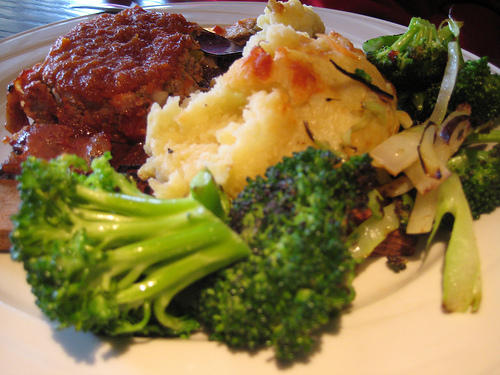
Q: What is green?
A: Broccoli.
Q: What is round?
A: Plate.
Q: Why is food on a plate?
A: To be eaten.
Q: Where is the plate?
A: On a table.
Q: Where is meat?
A: On the plate.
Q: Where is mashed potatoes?
A: On plate.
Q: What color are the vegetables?
A: Green.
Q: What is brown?
A: Meat.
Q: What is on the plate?
A: Food.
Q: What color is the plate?
A: White.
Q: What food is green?
A: The broccoli.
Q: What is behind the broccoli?
A: Mashed potatoes.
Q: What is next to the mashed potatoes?
A: Meatloaf.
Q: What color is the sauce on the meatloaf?
A: Red.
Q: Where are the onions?
A: On the right.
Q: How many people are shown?
A: Zero.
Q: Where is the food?
A: On the plate.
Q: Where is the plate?
A: On a table.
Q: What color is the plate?
A: White.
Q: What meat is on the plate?
A: Meatloaf.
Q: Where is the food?
A: On the plate.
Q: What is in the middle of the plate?
A: Mashed potatoes.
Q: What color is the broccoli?
A: Green.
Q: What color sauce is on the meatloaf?
A: Red.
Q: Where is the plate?
A: On the table.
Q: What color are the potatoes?
A: White.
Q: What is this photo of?
A: A plate of food.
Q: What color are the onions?
A: White.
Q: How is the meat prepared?
A: Mushy.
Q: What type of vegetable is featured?
A: Broccoli.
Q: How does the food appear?
A: Shiny.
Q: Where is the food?
A: On the plate.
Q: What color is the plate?
A: White.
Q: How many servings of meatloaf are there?
A: One.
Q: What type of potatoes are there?
A: Mashed.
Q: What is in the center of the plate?
A: Mashed potatoes.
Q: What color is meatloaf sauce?
A: Red.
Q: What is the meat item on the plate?
A: Meatloaf.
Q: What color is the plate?
A: White.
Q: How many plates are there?
A: One.